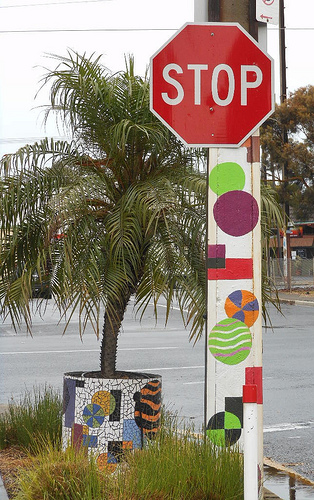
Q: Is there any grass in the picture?
A: Yes, there is grass.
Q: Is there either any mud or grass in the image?
A: Yes, there is grass.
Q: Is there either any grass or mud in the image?
A: Yes, there is grass.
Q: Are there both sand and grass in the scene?
A: No, there is grass but no sand.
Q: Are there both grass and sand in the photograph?
A: No, there is grass but no sand.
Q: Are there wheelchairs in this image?
A: No, there are no wheelchairs.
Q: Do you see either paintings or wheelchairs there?
A: No, there are no wheelchairs or paintings.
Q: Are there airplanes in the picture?
A: No, there are no airplanes.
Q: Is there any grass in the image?
A: Yes, there is grass.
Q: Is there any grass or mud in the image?
A: Yes, there is grass.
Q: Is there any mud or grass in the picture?
A: Yes, there is grass.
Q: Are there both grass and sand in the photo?
A: No, there is grass but no sand.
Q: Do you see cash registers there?
A: No, there are no cash registers.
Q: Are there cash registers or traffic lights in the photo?
A: No, there are no cash registers or traffic lights.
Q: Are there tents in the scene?
A: No, there are no tents.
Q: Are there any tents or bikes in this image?
A: No, there are no tents or bikes.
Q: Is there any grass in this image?
A: Yes, there is grass.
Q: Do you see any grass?
A: Yes, there is grass.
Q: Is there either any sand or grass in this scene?
A: Yes, there is grass.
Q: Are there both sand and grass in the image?
A: No, there is grass but no sand.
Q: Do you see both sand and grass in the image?
A: No, there is grass but no sand.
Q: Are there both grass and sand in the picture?
A: No, there is grass but no sand.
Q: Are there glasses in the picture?
A: No, there are no glasses.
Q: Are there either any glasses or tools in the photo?
A: No, there are no glasses or tools.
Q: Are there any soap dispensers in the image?
A: No, there are no soap dispensers.